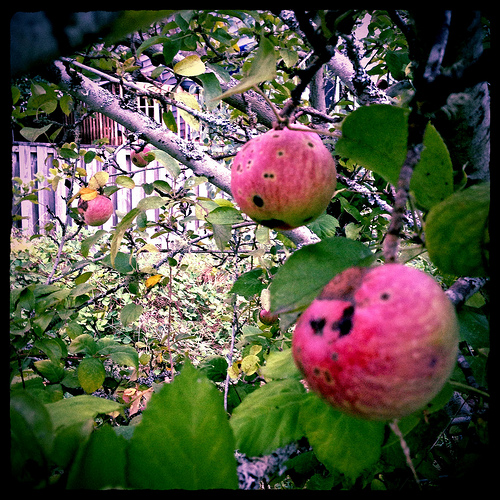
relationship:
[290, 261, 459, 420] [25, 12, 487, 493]
apple in tree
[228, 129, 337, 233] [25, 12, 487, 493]
apple in tree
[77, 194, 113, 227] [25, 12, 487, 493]
black dots in tree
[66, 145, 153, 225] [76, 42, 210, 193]
fence behind tree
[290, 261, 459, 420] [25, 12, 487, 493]
apple on tree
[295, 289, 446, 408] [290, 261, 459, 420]
black dots on apple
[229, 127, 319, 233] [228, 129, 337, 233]
black dots on apple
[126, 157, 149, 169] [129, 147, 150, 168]
black dots on black dots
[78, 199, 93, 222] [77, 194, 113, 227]
black dots on black dots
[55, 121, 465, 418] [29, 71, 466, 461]
apples on tree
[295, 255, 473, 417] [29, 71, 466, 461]
apple on tree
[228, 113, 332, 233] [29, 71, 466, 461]
apple on tree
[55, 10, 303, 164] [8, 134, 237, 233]
house behind fence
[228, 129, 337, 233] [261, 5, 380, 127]
apple attached to branch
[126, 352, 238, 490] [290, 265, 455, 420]
leaf near pink fruit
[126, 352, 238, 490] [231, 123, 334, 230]
leaf near pink fruit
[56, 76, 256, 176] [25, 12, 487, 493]
branch of tree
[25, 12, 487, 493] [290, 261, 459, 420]
tree has apple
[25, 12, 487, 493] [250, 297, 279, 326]
tree has fruit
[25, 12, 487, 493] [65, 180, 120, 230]
tree has fruit